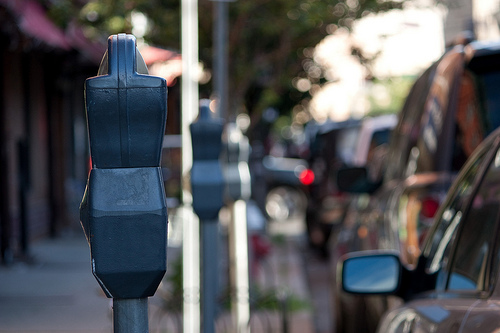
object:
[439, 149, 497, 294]
window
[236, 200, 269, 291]
hydrant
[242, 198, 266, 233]
cap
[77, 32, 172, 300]
meter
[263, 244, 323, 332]
curb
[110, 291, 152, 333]
pole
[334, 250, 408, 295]
glass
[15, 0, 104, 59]
roof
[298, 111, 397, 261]
truck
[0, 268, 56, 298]
ground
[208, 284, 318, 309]
grass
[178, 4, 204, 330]
pole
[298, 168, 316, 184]
glare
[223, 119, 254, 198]
parking meter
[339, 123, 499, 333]
car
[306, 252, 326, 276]
ground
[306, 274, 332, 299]
ground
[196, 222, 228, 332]
pole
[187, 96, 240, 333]
meter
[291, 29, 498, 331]
road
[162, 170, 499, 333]
street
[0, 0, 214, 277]
building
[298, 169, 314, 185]
circle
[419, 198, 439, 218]
circle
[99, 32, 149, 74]
meter top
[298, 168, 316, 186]
light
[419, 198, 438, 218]
light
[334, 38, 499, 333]
cars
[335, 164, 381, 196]
sideview mirror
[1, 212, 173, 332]
sidewalk